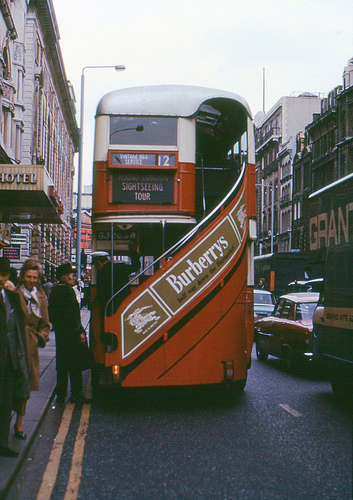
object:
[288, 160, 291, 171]
window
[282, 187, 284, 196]
window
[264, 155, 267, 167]
window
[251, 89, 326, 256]
building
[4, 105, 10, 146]
window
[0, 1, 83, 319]
building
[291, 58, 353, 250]
building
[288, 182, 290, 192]
window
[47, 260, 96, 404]
person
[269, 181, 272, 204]
window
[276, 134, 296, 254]
building